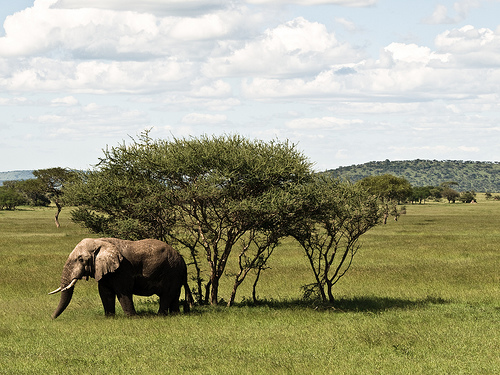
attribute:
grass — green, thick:
[2, 195, 495, 374]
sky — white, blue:
[3, 0, 500, 189]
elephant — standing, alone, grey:
[50, 235, 188, 316]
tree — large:
[58, 140, 308, 302]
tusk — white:
[61, 276, 79, 298]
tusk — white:
[49, 284, 63, 295]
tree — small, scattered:
[358, 173, 412, 222]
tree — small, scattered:
[445, 190, 466, 204]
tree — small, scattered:
[34, 167, 88, 225]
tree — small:
[0, 183, 36, 215]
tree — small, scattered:
[456, 193, 479, 206]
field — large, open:
[4, 192, 498, 375]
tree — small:
[416, 188, 444, 203]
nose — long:
[53, 265, 80, 320]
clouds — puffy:
[0, 8, 495, 137]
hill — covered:
[314, 157, 497, 203]